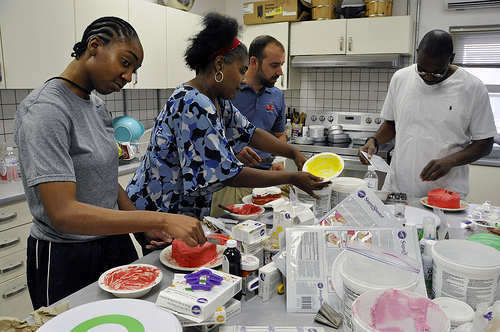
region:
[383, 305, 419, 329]
a stained container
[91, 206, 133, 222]
right arm of a lady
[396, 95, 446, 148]
part of a white cloth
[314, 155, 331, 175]
a yellow stained container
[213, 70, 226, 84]
a shiny earring on an ear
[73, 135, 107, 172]
part of a grey t shirt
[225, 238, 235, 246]
part of a white bottletop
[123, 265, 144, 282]
a red stained container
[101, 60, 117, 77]
right cheek of a lady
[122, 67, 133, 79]
nose of a lady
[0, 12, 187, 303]
lady icing cake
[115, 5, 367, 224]
lady holding dish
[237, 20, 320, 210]
man icing cake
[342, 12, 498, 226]
man holding paper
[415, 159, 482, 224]
small pink cake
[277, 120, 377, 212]
bowl with yellow icing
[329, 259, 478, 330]
pink icing in white container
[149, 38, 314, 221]
lady wearing blue print top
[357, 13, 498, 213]
man wearing white shirt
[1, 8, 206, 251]
lady wearing grey shirt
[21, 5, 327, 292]
People in kitchen cooking.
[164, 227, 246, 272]
Cake with red icing.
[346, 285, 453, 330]
Plastic bucket with pink icing.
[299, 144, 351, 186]
Bowl with yellow icing.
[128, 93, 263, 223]
Woman dressed in blue, black and white print blouse.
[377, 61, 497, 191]
Young man dressed in white t-shirt.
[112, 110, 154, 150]
Blue plastic bowl in dish drain.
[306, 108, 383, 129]
Control knobs on back of stove.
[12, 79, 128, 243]
Young lady dressed in gray t-shirt.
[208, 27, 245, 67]
A red hair band around woman's head.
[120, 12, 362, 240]
lady holding bowl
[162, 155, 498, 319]
cake supplies on table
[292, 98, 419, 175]
white stop in background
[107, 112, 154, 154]
blue dish in background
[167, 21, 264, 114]
lady wearing red headband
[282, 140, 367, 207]
yellow icing in bowl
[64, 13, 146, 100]
A person with corn rows in their hair.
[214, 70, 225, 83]
Large silver circular earring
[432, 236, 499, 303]
Tall white plastic bowl with writing on it.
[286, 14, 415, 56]
Two cabinet doors over the oven.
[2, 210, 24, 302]
4 silver drawer handles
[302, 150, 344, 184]
Small bowl with bright yellow substance inside.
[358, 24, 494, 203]
Man looking down at table.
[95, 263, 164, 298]
small bowl with red substance inside.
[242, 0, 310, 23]
opened cardboard box on cabinets.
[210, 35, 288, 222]
Man in blue shirt